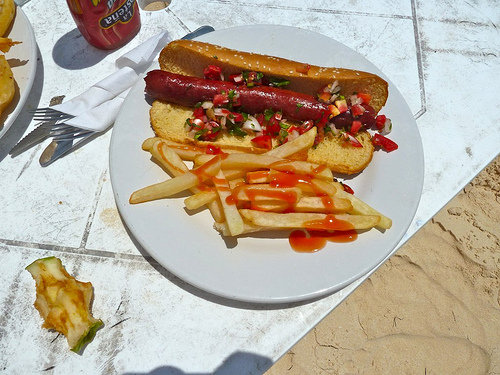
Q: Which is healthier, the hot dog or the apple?
A: The apple is healthier than the hot dog.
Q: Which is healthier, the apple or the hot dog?
A: The apple is healthier than the hot dog.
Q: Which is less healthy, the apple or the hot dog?
A: The hot dog is less healthy than the apple.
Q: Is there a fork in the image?
A: Yes, there is a fork.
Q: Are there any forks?
A: Yes, there is a fork.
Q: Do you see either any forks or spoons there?
A: Yes, there is a fork.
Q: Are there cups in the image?
A: No, there are no cups.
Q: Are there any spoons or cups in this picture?
A: No, there are no cups or spoons.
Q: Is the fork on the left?
A: Yes, the fork is on the left of the image.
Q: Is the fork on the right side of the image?
A: No, the fork is on the left of the image.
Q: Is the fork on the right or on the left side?
A: The fork is on the left of the image.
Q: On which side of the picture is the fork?
A: The fork is on the left of the image.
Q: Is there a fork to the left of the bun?
A: Yes, there is a fork to the left of the bun.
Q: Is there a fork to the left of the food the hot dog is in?
A: Yes, there is a fork to the left of the bun.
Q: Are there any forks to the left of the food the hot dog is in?
A: Yes, there is a fork to the left of the bun.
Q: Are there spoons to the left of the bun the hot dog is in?
A: No, there is a fork to the left of the bun.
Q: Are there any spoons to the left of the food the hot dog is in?
A: No, there is a fork to the left of the bun.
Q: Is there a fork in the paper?
A: Yes, there is a fork in the paper.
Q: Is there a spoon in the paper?
A: No, there is a fork in the paper.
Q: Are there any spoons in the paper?
A: No, there is a fork in the paper.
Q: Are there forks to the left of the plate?
A: Yes, there is a fork to the left of the plate.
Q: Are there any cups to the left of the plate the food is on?
A: No, there is a fork to the left of the plate.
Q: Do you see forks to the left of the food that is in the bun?
A: Yes, there is a fork to the left of the hot dog.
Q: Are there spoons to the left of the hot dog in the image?
A: No, there is a fork to the left of the hot dog.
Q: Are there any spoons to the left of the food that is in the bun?
A: No, there is a fork to the left of the hot dog.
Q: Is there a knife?
A: Yes, there is a knife.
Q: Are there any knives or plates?
A: Yes, there is a knife.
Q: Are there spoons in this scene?
A: No, there are no spoons.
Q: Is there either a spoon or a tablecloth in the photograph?
A: No, there are no spoons or tablecloths.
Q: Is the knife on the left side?
A: Yes, the knife is on the left of the image.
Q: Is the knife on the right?
A: No, the knife is on the left of the image.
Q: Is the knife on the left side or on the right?
A: The knife is on the left of the image.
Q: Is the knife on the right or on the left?
A: The knife is on the left of the image.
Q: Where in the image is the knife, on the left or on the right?
A: The knife is on the left of the image.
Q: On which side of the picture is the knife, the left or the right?
A: The knife is on the left of the image.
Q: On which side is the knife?
A: The knife is on the left of the image.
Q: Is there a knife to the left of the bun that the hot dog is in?
A: Yes, there is a knife to the left of the bun.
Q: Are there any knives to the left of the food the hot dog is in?
A: Yes, there is a knife to the left of the bun.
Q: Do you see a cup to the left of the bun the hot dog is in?
A: No, there is a knife to the left of the bun.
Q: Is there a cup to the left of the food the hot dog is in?
A: No, there is a knife to the left of the bun.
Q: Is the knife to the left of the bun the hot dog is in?
A: Yes, the knife is to the left of the bun.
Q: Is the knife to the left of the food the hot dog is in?
A: Yes, the knife is to the left of the bun.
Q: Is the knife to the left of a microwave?
A: No, the knife is to the left of the bun.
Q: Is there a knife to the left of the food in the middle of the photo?
A: Yes, there is a knife to the left of the food.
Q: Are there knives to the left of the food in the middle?
A: Yes, there is a knife to the left of the food.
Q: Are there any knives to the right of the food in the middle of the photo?
A: No, the knife is to the left of the food.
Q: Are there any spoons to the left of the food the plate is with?
A: No, there is a knife to the left of the food.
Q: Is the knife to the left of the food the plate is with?
A: Yes, the knife is to the left of the food.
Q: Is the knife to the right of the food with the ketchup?
A: No, the knife is to the left of the food.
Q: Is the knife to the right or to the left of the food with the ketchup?
A: The knife is to the left of the food.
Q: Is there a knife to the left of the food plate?
A: Yes, there is a knife to the left of the plate.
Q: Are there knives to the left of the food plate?
A: Yes, there is a knife to the left of the plate.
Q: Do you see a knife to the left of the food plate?
A: Yes, there is a knife to the left of the plate.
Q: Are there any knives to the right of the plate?
A: No, the knife is to the left of the plate.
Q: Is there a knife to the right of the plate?
A: No, the knife is to the left of the plate.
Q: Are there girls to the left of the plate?
A: No, there is a knife to the left of the plate.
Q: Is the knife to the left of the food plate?
A: Yes, the knife is to the left of the plate.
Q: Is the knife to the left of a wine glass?
A: No, the knife is to the left of the plate.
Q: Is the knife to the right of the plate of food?
A: No, the knife is to the left of the plate.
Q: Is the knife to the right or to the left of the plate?
A: The knife is to the left of the plate.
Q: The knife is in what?
A: The knife is in the paper.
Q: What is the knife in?
A: The knife is in the paper.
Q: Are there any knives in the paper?
A: Yes, there is a knife in the paper.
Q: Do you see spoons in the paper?
A: No, there is a knife in the paper.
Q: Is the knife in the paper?
A: Yes, the knife is in the paper.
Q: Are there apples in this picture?
A: Yes, there is an apple.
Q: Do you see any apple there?
A: Yes, there is an apple.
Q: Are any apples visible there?
A: Yes, there is an apple.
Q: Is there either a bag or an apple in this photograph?
A: Yes, there is an apple.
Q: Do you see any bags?
A: No, there are no bags.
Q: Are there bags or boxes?
A: No, there are no bags or boxes.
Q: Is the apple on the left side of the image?
A: Yes, the apple is on the left of the image.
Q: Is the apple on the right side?
A: No, the apple is on the left of the image.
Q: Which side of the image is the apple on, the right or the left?
A: The apple is on the left of the image.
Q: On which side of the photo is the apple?
A: The apple is on the left of the image.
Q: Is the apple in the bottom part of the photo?
A: Yes, the apple is in the bottom of the image.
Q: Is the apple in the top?
A: No, the apple is in the bottom of the image.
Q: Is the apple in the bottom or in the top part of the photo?
A: The apple is in the bottom of the image.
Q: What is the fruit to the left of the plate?
A: The fruit is an apple.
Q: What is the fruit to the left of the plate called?
A: The fruit is an apple.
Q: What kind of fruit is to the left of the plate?
A: The fruit is an apple.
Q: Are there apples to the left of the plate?
A: Yes, there is an apple to the left of the plate.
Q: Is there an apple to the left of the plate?
A: Yes, there is an apple to the left of the plate.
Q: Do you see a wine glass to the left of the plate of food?
A: No, there is an apple to the left of the plate.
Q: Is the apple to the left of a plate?
A: Yes, the apple is to the left of a plate.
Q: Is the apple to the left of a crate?
A: No, the apple is to the left of a plate.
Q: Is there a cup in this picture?
A: No, there are no cups.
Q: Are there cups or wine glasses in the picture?
A: No, there are no cups or wine glasses.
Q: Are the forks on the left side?
A: Yes, the forks are on the left of the image.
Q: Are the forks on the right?
A: No, the forks are on the left of the image.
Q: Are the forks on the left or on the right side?
A: The forks are on the left of the image.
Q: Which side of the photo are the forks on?
A: The forks are on the left of the image.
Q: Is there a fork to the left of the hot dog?
A: Yes, there are forks to the left of the hot dog.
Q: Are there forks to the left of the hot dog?
A: Yes, there are forks to the left of the hot dog.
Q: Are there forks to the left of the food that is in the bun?
A: Yes, there are forks to the left of the hot dog.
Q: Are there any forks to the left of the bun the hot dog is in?
A: Yes, there are forks to the left of the bun.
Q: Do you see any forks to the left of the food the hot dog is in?
A: Yes, there are forks to the left of the bun.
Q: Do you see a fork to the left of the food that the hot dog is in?
A: Yes, there are forks to the left of the bun.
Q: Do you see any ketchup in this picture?
A: Yes, there is ketchup.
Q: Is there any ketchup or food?
A: Yes, there is ketchup.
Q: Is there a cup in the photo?
A: No, there are no cups.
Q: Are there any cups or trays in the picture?
A: No, there are no cups or trays.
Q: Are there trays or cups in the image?
A: No, there are no cups or trays.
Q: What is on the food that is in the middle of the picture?
A: The ketchup is on the food.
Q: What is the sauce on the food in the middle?
A: The sauce is ketchup.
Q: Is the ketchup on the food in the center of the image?
A: Yes, the ketchup is on the food.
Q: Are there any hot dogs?
A: Yes, there is a hot dog.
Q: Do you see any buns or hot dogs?
A: Yes, there is a hot dog.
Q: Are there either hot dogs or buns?
A: Yes, there is a hot dog.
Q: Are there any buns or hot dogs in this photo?
A: Yes, there is a hot dog.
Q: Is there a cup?
A: No, there are no cups.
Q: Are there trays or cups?
A: No, there are no cups or trays.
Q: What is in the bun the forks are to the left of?
A: The hot dog is in the bun.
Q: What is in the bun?
A: The hot dog is in the bun.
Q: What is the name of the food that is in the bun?
A: The food is a hot dog.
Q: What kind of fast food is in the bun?
A: The food is a hot dog.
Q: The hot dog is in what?
A: The hot dog is in the bun.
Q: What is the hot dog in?
A: The hot dog is in the bun.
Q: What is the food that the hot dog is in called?
A: The food is a bun.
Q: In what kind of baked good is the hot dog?
A: The hot dog is in the bun.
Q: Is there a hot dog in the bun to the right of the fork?
A: Yes, there is a hot dog in the bun.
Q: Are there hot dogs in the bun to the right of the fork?
A: Yes, there is a hot dog in the bun.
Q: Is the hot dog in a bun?
A: Yes, the hot dog is in a bun.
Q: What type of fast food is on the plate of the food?
A: The food is a hot dog.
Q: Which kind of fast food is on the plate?
A: The food is a hot dog.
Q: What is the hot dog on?
A: The hot dog is on the plate.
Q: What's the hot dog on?
A: The hot dog is on the plate.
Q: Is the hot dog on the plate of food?
A: Yes, the hot dog is on the plate.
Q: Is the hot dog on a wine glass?
A: No, the hot dog is on the plate.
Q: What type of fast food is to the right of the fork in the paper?
A: The food is a hot dog.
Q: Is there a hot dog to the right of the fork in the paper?
A: Yes, there is a hot dog to the right of the fork.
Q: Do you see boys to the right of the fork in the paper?
A: No, there is a hot dog to the right of the fork.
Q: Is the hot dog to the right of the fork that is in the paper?
A: Yes, the hot dog is to the right of the fork.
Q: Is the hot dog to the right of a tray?
A: No, the hot dog is to the right of the fork.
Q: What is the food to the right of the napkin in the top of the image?
A: The food is a hot dog.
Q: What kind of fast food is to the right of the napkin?
A: The food is a hot dog.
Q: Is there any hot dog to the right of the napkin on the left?
A: Yes, there is a hot dog to the right of the napkin.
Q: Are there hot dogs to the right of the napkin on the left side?
A: Yes, there is a hot dog to the right of the napkin.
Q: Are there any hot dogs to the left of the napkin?
A: No, the hot dog is to the right of the napkin.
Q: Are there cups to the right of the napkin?
A: No, there is a hot dog to the right of the napkin.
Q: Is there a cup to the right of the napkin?
A: No, there is a hot dog to the right of the napkin.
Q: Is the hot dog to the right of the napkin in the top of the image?
A: Yes, the hot dog is to the right of the napkin.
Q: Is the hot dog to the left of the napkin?
A: No, the hot dog is to the right of the napkin.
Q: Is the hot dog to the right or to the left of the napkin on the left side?
A: The hot dog is to the right of the napkin.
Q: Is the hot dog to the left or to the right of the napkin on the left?
A: The hot dog is to the right of the napkin.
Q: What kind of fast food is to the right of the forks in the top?
A: The food is a hot dog.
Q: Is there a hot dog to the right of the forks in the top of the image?
A: Yes, there is a hot dog to the right of the forks.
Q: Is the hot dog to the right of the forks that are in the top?
A: Yes, the hot dog is to the right of the forks.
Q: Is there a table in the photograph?
A: Yes, there is a table.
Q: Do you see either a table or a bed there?
A: Yes, there is a table.